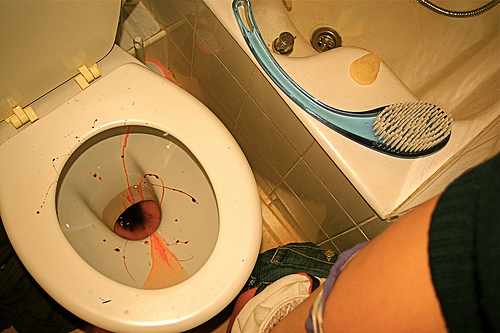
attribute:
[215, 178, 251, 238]
toilet seat — white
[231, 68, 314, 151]
tiles — Green 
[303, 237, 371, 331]
underwear — purple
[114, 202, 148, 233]
blood — Red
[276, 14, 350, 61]
faucet — silver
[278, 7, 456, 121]
tub — bathtub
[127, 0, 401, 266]
tiles — Square , beige 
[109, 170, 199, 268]
blood — Red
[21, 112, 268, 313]
toilet bowl — White 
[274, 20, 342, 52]
drain — Silver 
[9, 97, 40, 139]
hinge — yellow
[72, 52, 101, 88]
hinge — yellow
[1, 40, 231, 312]
toilet — beige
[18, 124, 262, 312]
toilet — White 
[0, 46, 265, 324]
bowl — toilet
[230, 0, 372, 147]
handle — blue 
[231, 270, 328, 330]
tennis shoe — white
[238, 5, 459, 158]
brush — blue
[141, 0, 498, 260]
bathtub — Beige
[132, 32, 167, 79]
toilet brush — White 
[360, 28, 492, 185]
showers — White 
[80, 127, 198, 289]
blood — Red